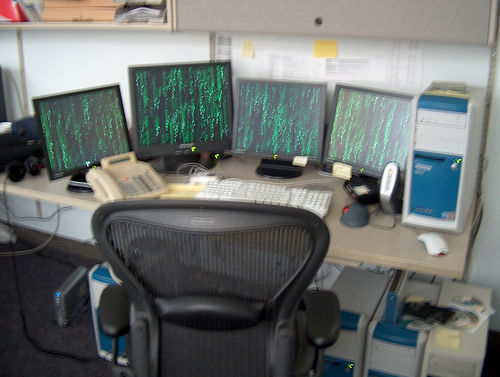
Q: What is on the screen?
A: Screensaver.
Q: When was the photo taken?
A: During work.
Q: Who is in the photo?
A: Nobody.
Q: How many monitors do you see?
A: Four.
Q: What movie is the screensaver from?
A: The Matrix.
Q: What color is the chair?
A: Black.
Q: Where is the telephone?
A: On the desk.